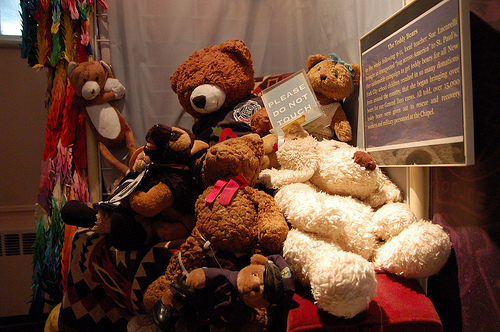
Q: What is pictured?
A: Teddy bears.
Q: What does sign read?
A: Please do not touch.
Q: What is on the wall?
A: A sign.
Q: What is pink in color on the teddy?
A: A bow.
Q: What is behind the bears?
A: A white color sheet.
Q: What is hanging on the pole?
A: A bear.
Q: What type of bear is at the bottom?
A: A police bear.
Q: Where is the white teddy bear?
A: Below the sign board.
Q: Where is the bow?
A: On bears neck.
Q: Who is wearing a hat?
A: A teddy.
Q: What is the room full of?
A: Teddy bears.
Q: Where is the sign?
A: Pole.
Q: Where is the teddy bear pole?
A: Against wall.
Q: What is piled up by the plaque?
A: Stuffed animals.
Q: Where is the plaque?
A: Wall.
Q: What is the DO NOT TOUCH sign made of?
A: Plastic.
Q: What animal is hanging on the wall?
A: Bear.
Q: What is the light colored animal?
A: Dog.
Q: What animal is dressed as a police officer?
A: Bear.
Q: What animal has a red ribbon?
A: Bear.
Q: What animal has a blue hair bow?
A: Bear.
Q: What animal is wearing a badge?
A: Bear.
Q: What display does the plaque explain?
A: Bear display.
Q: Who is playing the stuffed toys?
A: No one.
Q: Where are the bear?
A: On a table.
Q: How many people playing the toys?
A: Zero.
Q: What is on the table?
A: Teddy bears.